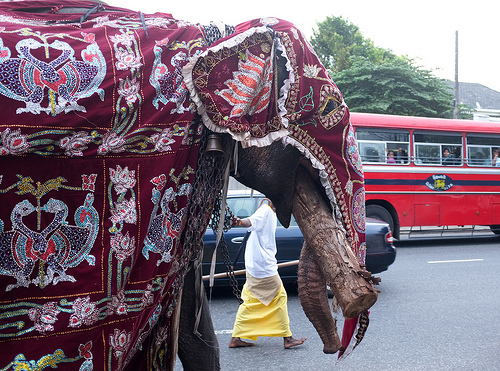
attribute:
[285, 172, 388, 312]
wood — large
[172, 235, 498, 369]
street — grey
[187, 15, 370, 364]
cloth hood — covering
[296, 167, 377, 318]
log — brown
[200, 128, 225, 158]
bell — dark brown, worn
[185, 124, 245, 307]
chains — heavy, worn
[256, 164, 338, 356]
man — barefoot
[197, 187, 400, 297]
sedan — dark blue, behind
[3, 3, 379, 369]
elephant — large, walking, dressed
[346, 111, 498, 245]
bus — red, used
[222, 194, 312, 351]
person — walking, shoeless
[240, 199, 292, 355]
man — holding